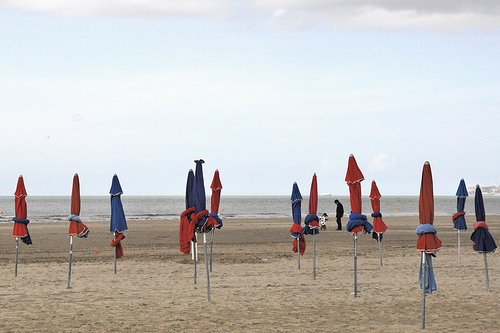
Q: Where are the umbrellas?
A: In the sand.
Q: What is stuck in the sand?
A: Umbrellas.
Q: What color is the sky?
A: Blue.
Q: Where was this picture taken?
A: At the beach.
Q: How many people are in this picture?
A: Two.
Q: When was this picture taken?
A: Day time.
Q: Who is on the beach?
A: The man and child.